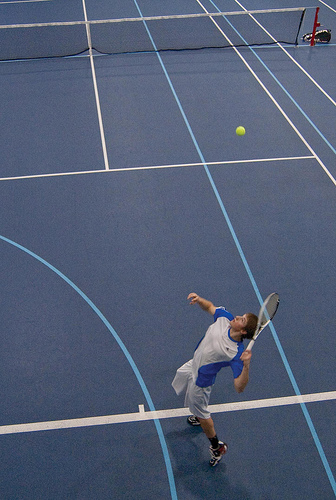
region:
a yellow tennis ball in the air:
[233, 121, 248, 137]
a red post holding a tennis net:
[308, 3, 322, 49]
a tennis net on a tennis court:
[0, 4, 316, 65]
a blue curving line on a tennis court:
[0, 233, 177, 498]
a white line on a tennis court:
[0, 389, 334, 433]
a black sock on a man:
[207, 432, 219, 449]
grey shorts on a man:
[167, 357, 213, 423]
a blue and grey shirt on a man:
[188, 305, 245, 388]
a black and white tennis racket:
[246, 289, 281, 350]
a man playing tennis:
[168, 289, 259, 468]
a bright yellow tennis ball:
[233, 125, 246, 138]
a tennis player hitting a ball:
[170, 285, 282, 474]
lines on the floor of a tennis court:
[7, 236, 170, 461]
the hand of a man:
[184, 291, 200, 306]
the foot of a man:
[199, 441, 229, 472]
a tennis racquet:
[239, 290, 282, 362]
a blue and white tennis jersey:
[185, 305, 247, 392]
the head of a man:
[226, 312, 261, 342]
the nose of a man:
[231, 314, 242, 322]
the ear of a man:
[238, 328, 248, 336]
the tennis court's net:
[0, 6, 306, 61]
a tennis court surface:
[0, 0, 335, 498]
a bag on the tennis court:
[299, 28, 331, 43]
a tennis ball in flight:
[235, 125, 245, 136]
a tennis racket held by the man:
[243, 291, 279, 353]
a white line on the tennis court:
[0, 390, 335, 434]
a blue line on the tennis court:
[0, 234, 178, 498]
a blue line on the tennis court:
[132, 0, 334, 499]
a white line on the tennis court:
[233, 0, 334, 106]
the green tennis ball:
[229, 122, 250, 140]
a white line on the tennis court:
[78, 416, 91, 426]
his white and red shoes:
[208, 442, 226, 465]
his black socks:
[207, 431, 220, 445]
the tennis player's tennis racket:
[254, 290, 281, 333]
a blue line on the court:
[298, 424, 325, 448]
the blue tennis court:
[36, 444, 91, 476]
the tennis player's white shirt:
[197, 342, 216, 366]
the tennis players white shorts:
[194, 386, 207, 408]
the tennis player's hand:
[188, 290, 200, 306]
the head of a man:
[216, 299, 273, 346]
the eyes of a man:
[229, 308, 257, 335]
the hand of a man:
[175, 290, 208, 317]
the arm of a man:
[185, 266, 245, 326]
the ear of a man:
[229, 316, 263, 340]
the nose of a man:
[222, 308, 244, 332]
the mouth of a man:
[225, 314, 239, 333]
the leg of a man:
[188, 386, 231, 472]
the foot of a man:
[197, 436, 233, 473]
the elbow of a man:
[221, 366, 269, 401]